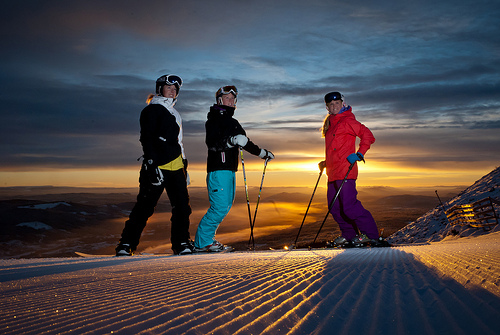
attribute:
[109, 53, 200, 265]
person — female, woman, skiier, skier, skiing, standing, looking, staring, smiling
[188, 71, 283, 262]
person — woman, female, skier, skiing, smiling, staring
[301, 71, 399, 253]
person — female, woman, skier, skiing, standing, looking, staring, smiling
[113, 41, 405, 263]
people — skiers, smiling, standing